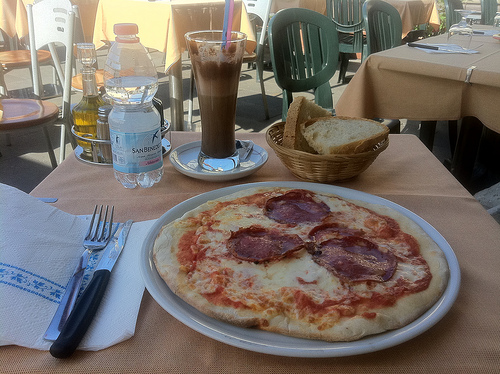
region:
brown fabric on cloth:
[399, 133, 431, 170]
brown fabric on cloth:
[387, 170, 410, 201]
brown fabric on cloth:
[159, 173, 187, 201]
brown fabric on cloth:
[143, 325, 183, 352]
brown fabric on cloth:
[107, 344, 133, 368]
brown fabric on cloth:
[451, 327, 488, 363]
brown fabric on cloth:
[388, 47, 414, 74]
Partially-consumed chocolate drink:
[183, 0, 244, 171]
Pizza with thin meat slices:
[150, 182, 447, 338]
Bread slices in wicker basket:
[265, 95, 386, 176]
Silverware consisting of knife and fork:
[41, 202, 131, 353]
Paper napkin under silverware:
[0, 175, 155, 345]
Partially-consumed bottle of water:
[100, 40, 160, 185]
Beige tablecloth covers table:
[0, 130, 499, 370]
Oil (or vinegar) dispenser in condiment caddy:
[70, 45, 100, 150]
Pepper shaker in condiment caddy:
[95, 100, 110, 155]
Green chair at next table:
[266, 5, 338, 120]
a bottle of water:
[99, 12, 170, 190]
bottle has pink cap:
[99, 16, 171, 196]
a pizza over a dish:
[134, 170, 470, 365]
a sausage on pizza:
[220, 217, 307, 264]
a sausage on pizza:
[313, 230, 399, 285]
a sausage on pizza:
[261, 177, 332, 231]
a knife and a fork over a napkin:
[41, 194, 136, 361]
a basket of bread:
[259, 90, 399, 175]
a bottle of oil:
[65, 36, 105, 163]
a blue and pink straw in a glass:
[179, 1, 251, 176]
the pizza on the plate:
[152, 185, 449, 340]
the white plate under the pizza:
[139, 180, 460, 356]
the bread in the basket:
[282, 95, 389, 153]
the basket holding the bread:
[265, 120, 389, 182]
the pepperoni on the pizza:
[227, 189, 397, 283]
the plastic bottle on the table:
[103, 22, 163, 189]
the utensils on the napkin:
[43, 203, 133, 358]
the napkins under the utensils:
[0, 181, 160, 351]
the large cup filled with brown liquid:
[184, 0, 246, 170]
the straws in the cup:
[220, 0, 233, 53]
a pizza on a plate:
[154, 185, 455, 356]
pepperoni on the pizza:
[328, 240, 385, 282]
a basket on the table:
[266, 101, 371, 168]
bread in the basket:
[303, 123, 367, 152]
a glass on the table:
[181, 49, 248, 170]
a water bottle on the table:
[117, 78, 163, 178]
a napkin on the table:
[3, 186, 153, 349]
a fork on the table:
[73, 186, 116, 242]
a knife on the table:
[90, 240, 150, 290]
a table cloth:
[41, 118, 493, 361]